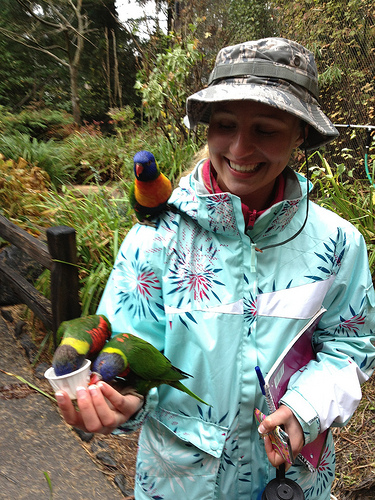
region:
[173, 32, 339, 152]
camouflaged green hat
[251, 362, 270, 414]
blue capped ball point pen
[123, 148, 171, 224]
green, yellow, blue, and orange parrot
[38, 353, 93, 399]
little white paper ramikin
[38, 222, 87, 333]
weathered wooden fence post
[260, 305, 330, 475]
spiral bound magenta note book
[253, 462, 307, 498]
blue plastic bottle with a black plastic cover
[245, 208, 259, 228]
pink metal zipper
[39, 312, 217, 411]
two green, blue, black, yellow, and orange parrots eating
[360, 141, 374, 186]
green hose tube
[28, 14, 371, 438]
A woman and three birds.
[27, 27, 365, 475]
A woman and three parakeets.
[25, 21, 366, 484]
A scientist doing an experiment with three birds.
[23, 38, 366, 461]
A woman and three birds in the woods.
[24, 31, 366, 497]
A woman recording her experiment with three birds.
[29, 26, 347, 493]
A scientist conducting a study of three birds.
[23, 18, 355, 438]
A woman with three birds, two are drinking water.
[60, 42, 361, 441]
A woman taking her pet parakeets for a walk.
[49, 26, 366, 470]
A woman and three parkeets enjoying the wilderness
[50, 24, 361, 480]
A woman and three parakeets waiting for bad weather.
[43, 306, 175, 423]
colorful parrots are eating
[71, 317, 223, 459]
colorful parrots are eating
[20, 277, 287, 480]
colorful parrots are eating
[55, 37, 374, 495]
woman holding parrots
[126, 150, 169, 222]
parrot on shoulder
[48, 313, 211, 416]
two parrots in her hand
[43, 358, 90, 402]
white paper cup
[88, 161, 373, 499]
light blue jacket with floral print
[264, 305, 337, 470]
pink notebook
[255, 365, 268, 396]
pen with blue cap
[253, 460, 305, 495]
plastic water bottle hanging from her hand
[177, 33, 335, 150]
camouflage bucket hat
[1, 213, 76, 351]
wooden fence in background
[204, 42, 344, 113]
hat on a lady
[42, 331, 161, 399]
two birds on lady's arm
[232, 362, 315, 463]
object on lady's hand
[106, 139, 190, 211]
bird on lady's shoulder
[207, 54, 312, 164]
lady looking at birds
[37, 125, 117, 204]
green grass behind lady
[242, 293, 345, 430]
notebook in lady's hand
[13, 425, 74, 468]
street below the lady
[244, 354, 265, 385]
blue cap on pen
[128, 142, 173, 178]
blue head of the bird